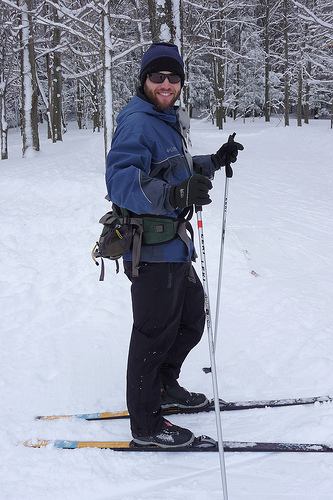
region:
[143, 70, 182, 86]
dark sunglasses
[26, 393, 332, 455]
two long yellow and black skis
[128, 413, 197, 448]
black sneaker with a red lace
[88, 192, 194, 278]
a green fanny pack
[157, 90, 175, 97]
a toothy grin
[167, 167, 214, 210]
one warm black winter glove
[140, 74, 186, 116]
a bushy brown beard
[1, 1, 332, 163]
snow covered trees in the background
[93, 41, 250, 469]
this man is wearing skis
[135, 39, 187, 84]
a black and blue ski cap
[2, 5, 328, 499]
the photo was taken outdsie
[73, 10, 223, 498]
the man is wearing clothes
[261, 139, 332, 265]
snow is on the ground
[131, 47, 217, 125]
the man is wearing glasses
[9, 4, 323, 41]
the tree are leafless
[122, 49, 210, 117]
the man is looking at the camera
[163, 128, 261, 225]
the man has gloves on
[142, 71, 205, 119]
the man is smiling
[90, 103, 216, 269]
the man has a blue jacket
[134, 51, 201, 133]
the man has beards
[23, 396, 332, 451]
skis on man's feet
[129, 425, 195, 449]
man's right ski boot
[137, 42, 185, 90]
man's blue stocking cap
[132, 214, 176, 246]
man's green fanny pack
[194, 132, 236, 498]
ski poles in man's hands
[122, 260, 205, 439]
man's black ski pants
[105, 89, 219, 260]
man's blue ski coat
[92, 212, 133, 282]
man's tool pack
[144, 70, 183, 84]
sunglasses on man's face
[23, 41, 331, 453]
man wearing skis in snow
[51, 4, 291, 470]
skier standing on flat snow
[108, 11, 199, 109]
skier wearing blue and black knit hat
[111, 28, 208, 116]
bearded skier with toothy smile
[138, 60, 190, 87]
skier wearing dark sunglasses with black frames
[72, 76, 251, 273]
skier wearing a jacket of grey and blue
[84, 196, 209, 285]
skier wearing waistpack with many straps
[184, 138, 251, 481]
skier holding silver poles with writing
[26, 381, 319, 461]
black, blue and tan ski covered with some snow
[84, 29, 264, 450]
skier wearing black pants, gloves and shoes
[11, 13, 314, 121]
skier in front of trees covered in snow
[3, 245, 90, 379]
snow covering the ground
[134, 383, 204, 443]
man wearing black shoes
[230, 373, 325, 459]
snow on man's skis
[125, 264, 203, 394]
man wearing black pants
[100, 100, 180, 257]
man wearing a blue jacket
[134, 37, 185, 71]
man wearing blue and black beanie hat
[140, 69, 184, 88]
dark sunglasses on man's face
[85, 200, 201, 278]
pack tied around man's waist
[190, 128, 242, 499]
man holding ski poles in his hands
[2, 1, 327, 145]
snow on trees behind man